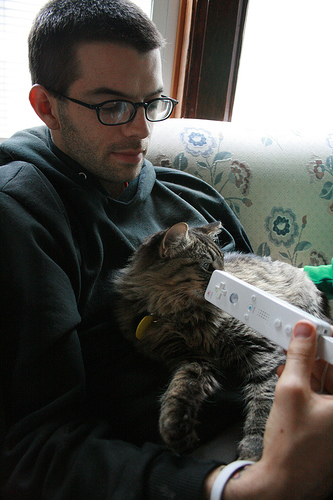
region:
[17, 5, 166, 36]
man with nice haircut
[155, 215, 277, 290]
cat sitting on man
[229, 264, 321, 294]
rump of striped cat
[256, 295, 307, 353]
man holding white controller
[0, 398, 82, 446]
man wearing black hoodie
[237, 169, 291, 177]
man sitting on flowered sofa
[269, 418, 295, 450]
man has spot on hand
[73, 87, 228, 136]
man wearing black glasses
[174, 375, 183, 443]
cat with furry paw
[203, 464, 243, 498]
white band on mans wrist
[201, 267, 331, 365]
a Wii remote in a man's hand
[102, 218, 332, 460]
a fluffy gray cat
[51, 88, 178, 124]
glasses on a man's face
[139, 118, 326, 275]
a floral couch behind a man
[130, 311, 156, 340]
a yellow tag on a cat's neck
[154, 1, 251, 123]
a window behind a man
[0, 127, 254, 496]
a black sweatshirt on a man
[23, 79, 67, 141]
an ear on a man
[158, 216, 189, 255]
a cat ear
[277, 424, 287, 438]
a mole on a man's hand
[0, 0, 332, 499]
Man wearing black glasses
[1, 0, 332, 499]
Man holding white game controller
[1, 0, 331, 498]
Man wearing black hoodie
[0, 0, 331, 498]
Man wearing white bracelette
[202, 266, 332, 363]
White game controller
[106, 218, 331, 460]
Brown and black cat wearing yellow tag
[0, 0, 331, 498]
Man holding black and brown cat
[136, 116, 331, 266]
Couch with floral design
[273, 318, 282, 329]
Round button on white controller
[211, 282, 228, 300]
Cross button on white controller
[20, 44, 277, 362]
man seated with cat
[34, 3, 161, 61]
short dark hair on man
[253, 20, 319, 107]
sunlight through window glass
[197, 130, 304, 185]
flower print on back of couch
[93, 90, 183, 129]
black rimmed glasses on face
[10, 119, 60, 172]
hood on back of sweatshirt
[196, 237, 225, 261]
stripes on cat's head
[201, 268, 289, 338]
white game control with buttons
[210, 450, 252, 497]
white bracelet on wrist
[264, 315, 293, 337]
white buttons on game control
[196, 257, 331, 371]
A white WII remote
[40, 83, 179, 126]
A black pair of glasses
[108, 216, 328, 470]
A striped cat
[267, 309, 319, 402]
A man's thumb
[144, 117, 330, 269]
Printed flowers on a couch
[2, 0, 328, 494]
A man holding a cat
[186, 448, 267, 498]
A wrist-strap for a WII remote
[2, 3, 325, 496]
A man wearing glasses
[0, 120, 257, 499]
A dark colored sweatshirt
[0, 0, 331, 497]
A man looking at a cat